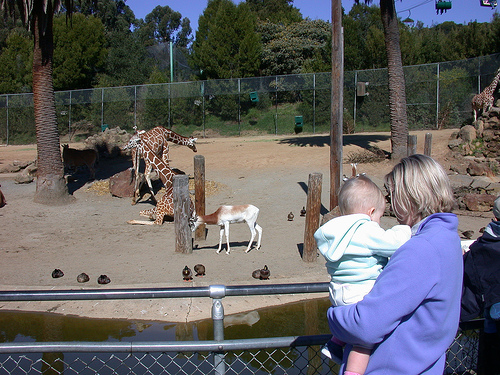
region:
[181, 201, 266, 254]
a brown and white goat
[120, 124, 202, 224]
a sitting giraffe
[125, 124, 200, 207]
a standing giraffe with it's head low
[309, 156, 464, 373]
a mother hold a child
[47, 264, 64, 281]
a duck sitting on the ground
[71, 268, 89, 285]
a duck sitting on the ground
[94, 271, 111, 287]
a duck sitting on the ground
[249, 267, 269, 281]
a duck sitting on the ground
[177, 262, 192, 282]
a duck standing on the ground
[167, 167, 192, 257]
a wooden pole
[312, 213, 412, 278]
a white baby girl's hoodie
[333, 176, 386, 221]
the head of a baby girl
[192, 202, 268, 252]
a baby giraffe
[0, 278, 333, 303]
a long gray pole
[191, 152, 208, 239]
a tall wooden post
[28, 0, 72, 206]
a tall tree trunk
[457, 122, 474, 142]
a big gray rock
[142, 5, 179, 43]
the top of a green tree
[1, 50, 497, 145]
a tall chain link fence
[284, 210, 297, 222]
a small bird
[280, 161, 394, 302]
baby has hoodie on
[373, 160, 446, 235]
woman has glasses on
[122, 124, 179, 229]
two giraffes are shown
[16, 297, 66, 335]
the water looks murky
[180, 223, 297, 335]
pigeons are present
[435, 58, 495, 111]
giraffe off by themselves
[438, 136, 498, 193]
rocks in animal's area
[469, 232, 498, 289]
the jacket is blue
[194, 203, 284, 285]
animal is brown and white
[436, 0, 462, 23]
a lift in the background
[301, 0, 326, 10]
The sky is deep blue.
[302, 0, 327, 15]
The sky is clear.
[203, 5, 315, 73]
Trees are in the background.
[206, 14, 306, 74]
The trees are green.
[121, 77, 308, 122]
A fence is in the background.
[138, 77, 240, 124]
The fence is made of metal.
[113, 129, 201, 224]
A giraffe is sitting down.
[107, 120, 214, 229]
Two giraffes are in the picture.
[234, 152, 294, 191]
The ground is made of dirt.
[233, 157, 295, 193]
The dirt is brown and gray.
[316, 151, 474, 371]
A woman holding a baby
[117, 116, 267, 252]
giraffes and deer in the zoo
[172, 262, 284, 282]
pigeons hanging around the giraffes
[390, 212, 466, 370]
The woman is wearing a lavender sweater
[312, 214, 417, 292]
the baby is wearing a hooded white sweater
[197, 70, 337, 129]
a fence in the background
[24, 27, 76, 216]
A brown tree trunk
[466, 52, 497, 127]
a beige and white giraffe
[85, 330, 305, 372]
A gray linked fence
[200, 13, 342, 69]
green lush trees